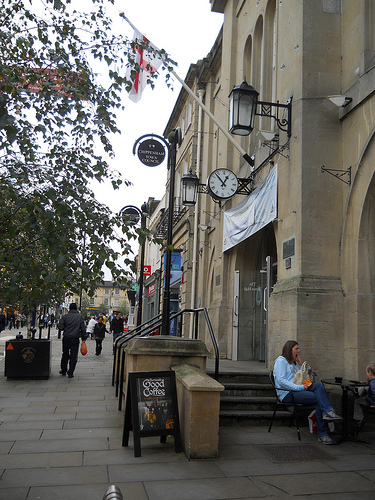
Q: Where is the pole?
A: Above the light.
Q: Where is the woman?
A: On the stoop.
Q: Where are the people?
A: On the sidewalk.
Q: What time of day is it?
A: Afternoon.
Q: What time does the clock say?
A: 12:53.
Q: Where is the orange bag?
A: In the man's right hand.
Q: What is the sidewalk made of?
A: Concrete blocks.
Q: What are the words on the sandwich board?
A: Good Coffee.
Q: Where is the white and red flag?
A: Hanging from the building.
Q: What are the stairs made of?
A: Concrete.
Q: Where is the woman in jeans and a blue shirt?
A: Sitting in a chair.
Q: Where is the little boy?
A: Sitting at a table.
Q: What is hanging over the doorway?
A: A banner.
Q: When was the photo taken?
A: Daytime.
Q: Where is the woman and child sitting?
A: Table.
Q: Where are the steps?
A: Behind the woman.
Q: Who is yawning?
A: Woman.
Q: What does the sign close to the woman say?
A: Good Coffee.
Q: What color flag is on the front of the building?
A: Red and white.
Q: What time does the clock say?
A: 12:53.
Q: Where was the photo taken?
A: On a city sidewalk.